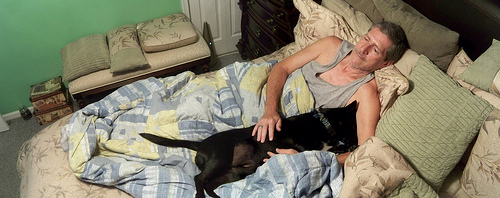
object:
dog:
[138, 100, 357, 198]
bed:
[16, 0, 500, 198]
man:
[251, 21, 407, 167]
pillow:
[370, 54, 492, 190]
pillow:
[342, 0, 459, 73]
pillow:
[457, 39, 500, 96]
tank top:
[301, 40, 374, 111]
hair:
[368, 21, 409, 62]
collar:
[315, 110, 336, 133]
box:
[30, 76, 66, 111]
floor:
[0, 119, 38, 198]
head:
[348, 21, 409, 70]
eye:
[363, 37, 368, 41]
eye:
[372, 48, 377, 53]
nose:
[359, 43, 372, 55]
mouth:
[355, 52, 363, 60]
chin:
[349, 57, 367, 70]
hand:
[250, 111, 283, 143]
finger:
[268, 124, 275, 141]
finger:
[261, 125, 269, 143]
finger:
[257, 126, 264, 142]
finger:
[251, 124, 260, 137]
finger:
[276, 117, 283, 132]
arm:
[264, 40, 319, 112]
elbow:
[272, 63, 290, 73]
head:
[322, 100, 357, 145]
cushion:
[105, 22, 148, 74]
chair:
[69, 11, 215, 109]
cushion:
[134, 11, 198, 52]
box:
[34, 105, 74, 125]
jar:
[18, 105, 32, 120]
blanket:
[63, 61, 343, 198]